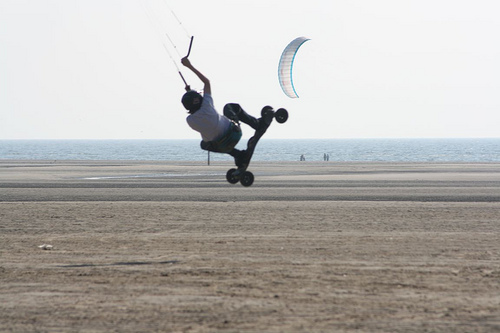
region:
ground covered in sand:
[216, 272, 413, 332]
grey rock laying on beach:
[27, 236, 64, 258]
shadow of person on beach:
[44, 250, 185, 287]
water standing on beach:
[65, 164, 205, 194]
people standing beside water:
[283, 147, 346, 174]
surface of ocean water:
[334, 139, 497, 161]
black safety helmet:
[177, 89, 203, 112]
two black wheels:
[216, 159, 267, 190]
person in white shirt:
[167, 78, 251, 173]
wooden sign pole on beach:
[203, 151, 211, 165]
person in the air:
[138, 44, 287, 190]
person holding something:
[124, 43, 291, 199]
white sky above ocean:
[361, 86, 442, 136]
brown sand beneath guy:
[218, 216, 355, 297]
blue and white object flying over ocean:
[254, 24, 346, 99]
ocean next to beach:
[117, 115, 163, 158]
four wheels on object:
[213, 99, 296, 211]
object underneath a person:
[220, 109, 310, 190]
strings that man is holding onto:
[132, 5, 191, 51]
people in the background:
[280, 137, 353, 200]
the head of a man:
[178, 84, 203, 114]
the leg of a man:
[219, 100, 259, 128]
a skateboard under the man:
[222, 102, 291, 188]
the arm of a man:
[188, 62, 213, 99]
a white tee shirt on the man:
[183, 91, 230, 147]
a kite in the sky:
[273, 27, 310, 104]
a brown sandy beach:
[0, 157, 498, 331]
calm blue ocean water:
[2, 136, 499, 163]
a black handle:
[176, 30, 201, 65]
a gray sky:
[1, 1, 499, 137]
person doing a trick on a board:
[124, 67, 319, 211]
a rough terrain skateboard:
[215, 101, 291, 192]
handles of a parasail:
[131, 5, 237, 122]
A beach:
[11, 170, 495, 332]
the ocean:
[2, 132, 499, 165]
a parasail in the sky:
[268, 29, 333, 105]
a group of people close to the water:
[297, 143, 332, 165]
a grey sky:
[6, 0, 491, 138]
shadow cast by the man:
[71, 233, 211, 273]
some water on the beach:
[53, 165, 223, 184]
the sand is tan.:
[1, 153, 497, 330]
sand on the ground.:
[2, 160, 497, 327]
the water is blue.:
[2, 130, 497, 167]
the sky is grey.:
[3, 1, 498, 139]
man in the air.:
[161, 35, 297, 188]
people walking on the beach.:
[295, 148, 338, 165]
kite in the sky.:
[276, 32, 314, 103]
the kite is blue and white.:
[275, 30, 312, 103]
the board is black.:
[222, 102, 289, 187]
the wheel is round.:
[259, 100, 293, 126]